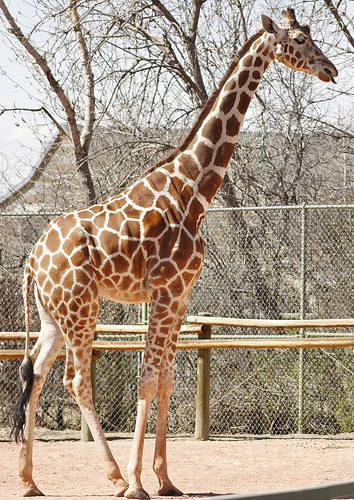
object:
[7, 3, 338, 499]
giraffe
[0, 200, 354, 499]
enclosure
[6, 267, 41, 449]
tail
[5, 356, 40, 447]
hair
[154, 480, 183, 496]
hoof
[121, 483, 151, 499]
hoof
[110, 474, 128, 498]
hoof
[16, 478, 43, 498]
hoof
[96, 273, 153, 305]
belly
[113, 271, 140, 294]
spot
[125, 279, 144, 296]
spot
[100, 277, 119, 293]
spot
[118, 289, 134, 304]
spot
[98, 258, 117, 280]
spot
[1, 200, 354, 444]
fence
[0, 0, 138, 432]
tree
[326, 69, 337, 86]
tongue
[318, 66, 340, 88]
mouth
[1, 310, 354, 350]
wood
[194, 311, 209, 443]
fence post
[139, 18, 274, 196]
mane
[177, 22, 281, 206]
neck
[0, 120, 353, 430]
building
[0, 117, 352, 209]
roof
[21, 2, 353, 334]
tree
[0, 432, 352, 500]
ground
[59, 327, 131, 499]
right leg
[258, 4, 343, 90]
head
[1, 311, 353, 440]
fence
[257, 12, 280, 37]
right ear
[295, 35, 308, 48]
right eye